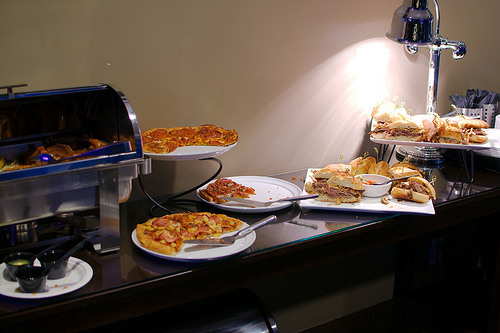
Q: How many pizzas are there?
A: 3.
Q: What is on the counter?
A: Food.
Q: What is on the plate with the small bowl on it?
A: Sandwiches.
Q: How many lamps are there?
A: 1.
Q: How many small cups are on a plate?
A: 3.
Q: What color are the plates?
A: White.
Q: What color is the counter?
A: Dark brown.